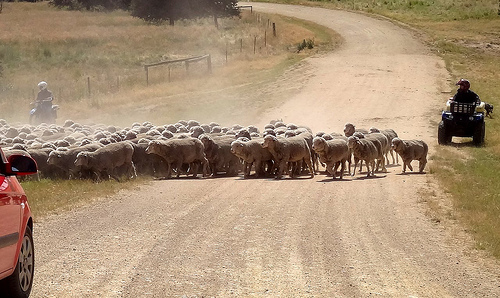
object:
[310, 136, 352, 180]
sheep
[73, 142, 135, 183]
sheep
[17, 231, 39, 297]
tire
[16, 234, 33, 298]
hubcap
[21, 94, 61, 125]
atv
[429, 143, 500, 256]
grass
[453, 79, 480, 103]
person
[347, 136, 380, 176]
sheep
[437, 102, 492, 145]
4-wheeler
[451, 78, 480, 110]
man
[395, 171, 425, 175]
shadow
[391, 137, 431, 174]
sheep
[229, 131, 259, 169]
sheep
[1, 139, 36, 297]
car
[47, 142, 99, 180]
sheep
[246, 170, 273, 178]
shadow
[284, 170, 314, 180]
shadow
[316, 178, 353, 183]
shadow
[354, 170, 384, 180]
shadow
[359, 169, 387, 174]
shadow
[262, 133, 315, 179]
sheep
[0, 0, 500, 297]
field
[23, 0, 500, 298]
crossing road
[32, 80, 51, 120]
man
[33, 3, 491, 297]
dirt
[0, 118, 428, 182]
sheep herd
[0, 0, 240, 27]
trees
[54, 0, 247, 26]
leaves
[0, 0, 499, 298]
ground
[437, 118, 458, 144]
tire